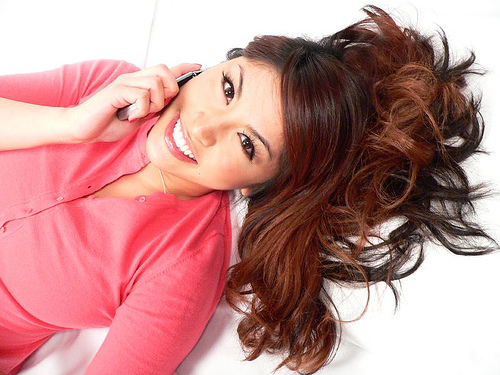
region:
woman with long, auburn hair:
[4, 0, 481, 372]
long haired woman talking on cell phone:
[3, 2, 488, 370]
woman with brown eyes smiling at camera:
[6, 21, 491, 352]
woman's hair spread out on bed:
[5, 15, 497, 372]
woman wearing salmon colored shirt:
[3, 30, 381, 368]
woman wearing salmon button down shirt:
[15, 12, 435, 357]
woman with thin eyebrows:
[18, 40, 381, 371]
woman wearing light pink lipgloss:
[1, 51, 362, 352]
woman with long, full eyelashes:
[2, 33, 283, 368]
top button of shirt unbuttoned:
[7, 25, 404, 373]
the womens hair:
[299, 92, 378, 168]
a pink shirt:
[58, 232, 133, 283]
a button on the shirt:
[21, 207, 37, 216]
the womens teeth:
[170, 131, 189, 148]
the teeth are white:
[174, 128, 189, 158]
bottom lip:
[160, 129, 182, 152]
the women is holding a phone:
[113, 104, 143, 119]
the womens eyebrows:
[260, 142, 277, 162]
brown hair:
[243, 301, 315, 366]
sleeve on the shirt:
[117, 316, 177, 358]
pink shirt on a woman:
[54, 234, 101, 280]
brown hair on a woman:
[311, 116, 376, 185]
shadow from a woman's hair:
[310, 282, 363, 373]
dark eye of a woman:
[234, 122, 265, 172]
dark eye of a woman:
[216, 68, 243, 110]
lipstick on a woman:
[158, 103, 205, 170]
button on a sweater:
[136, 188, 147, 206]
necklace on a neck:
[153, 165, 176, 200]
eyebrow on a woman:
[226, 60, 251, 100]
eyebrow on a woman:
[240, 117, 285, 177]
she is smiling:
[2, 11, 484, 371]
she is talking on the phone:
[3, 20, 377, 367]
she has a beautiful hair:
[246, 9, 495, 369]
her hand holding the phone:
[69, 62, 201, 145]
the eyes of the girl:
[221, 72, 258, 162]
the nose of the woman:
[192, 112, 217, 146]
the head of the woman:
[144, 37, 359, 189]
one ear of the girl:
[243, 181, 263, 196]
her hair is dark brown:
[236, 27, 498, 374]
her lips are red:
[164, 112, 198, 165]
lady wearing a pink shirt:
[6, 0, 496, 374]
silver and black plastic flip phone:
[113, 65, 216, 122]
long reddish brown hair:
[226, 10, 493, 372]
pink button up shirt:
[3, 57, 233, 374]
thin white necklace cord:
[142, 158, 182, 210]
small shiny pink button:
[134, 195, 147, 204]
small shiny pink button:
[54, 194, 70, 204]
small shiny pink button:
[19, 202, 37, 219]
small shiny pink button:
[0, 213, 10, 238]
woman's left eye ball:
[236, 118, 278, 173]